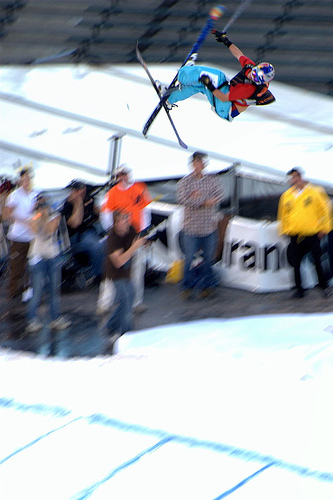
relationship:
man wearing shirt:
[176, 151, 226, 297] [174, 173, 222, 237]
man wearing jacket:
[278, 169, 332, 298] [278, 185, 331, 238]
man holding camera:
[104, 213, 155, 338] [137, 220, 169, 241]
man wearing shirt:
[5, 169, 33, 301] [7, 188, 33, 243]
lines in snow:
[1, 396, 333, 499] [2, 350, 331, 499]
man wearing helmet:
[166, 30, 276, 120] [250, 61, 277, 86]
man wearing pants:
[166, 30, 276, 120] [166, 64, 230, 119]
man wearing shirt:
[166, 30, 276, 120] [228, 57, 257, 112]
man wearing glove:
[166, 30, 276, 120] [213, 29, 231, 46]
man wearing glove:
[166, 30, 276, 120] [198, 75, 213, 91]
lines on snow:
[1, 396, 333, 499] [2, 350, 331, 499]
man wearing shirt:
[109, 170, 153, 228] [109, 184, 144, 233]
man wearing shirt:
[104, 213, 155, 338] [105, 227, 134, 277]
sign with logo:
[101, 196, 296, 294] [142, 210, 171, 253]